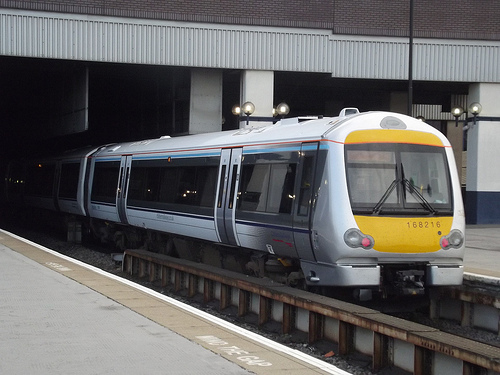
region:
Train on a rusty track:
[2, 107, 467, 304]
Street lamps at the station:
[228, 99, 481, 128]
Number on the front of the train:
[405, 219, 442, 231]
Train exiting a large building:
[2, 4, 497, 295]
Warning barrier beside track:
[0, 229, 354, 371]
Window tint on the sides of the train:
[0, 147, 325, 232]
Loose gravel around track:
[0, 232, 497, 371]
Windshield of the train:
[342, 141, 455, 221]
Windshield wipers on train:
[370, 161, 440, 219]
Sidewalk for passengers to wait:
[1, 229, 361, 374]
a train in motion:
[50, 90, 499, 365]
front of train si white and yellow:
[330, 105, 473, 302]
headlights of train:
[337, 215, 467, 264]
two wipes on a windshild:
[343, 139, 458, 220]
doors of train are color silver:
[43, 146, 315, 255]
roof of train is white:
[78, 108, 439, 145]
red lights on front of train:
[360, 229, 452, 253]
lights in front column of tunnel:
[210, 42, 296, 124]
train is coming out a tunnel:
[5, 2, 498, 293]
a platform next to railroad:
[0, 251, 470, 373]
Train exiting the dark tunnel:
[16, 108, 466, 293]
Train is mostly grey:
[25, 111, 470, 301]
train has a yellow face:
[342, 124, 463, 271]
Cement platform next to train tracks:
[0, 230, 117, 368]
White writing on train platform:
[195, 325, 275, 372]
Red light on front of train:
[355, 233, 371, 253]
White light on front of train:
[345, 231, 363, 247]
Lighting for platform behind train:
[445, 96, 484, 135]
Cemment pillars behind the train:
[238, 69, 280, 122]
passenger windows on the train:
[125, 158, 221, 223]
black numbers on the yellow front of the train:
[402, 218, 448, 233]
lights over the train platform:
[211, 95, 494, 137]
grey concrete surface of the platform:
[18, 290, 95, 372]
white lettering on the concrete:
[189, 317, 276, 372]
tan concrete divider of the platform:
[78, 260, 232, 345]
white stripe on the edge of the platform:
[182, 305, 232, 334]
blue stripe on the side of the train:
[128, 145, 320, 162]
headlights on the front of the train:
[326, 221, 479, 266]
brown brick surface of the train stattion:
[353, 5, 473, 32]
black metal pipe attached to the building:
[406, 10, 414, 111]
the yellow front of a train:
[346, 126, 458, 256]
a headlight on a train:
[343, 227, 363, 248]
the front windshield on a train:
[348, 145, 453, 213]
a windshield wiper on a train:
[397, 160, 440, 213]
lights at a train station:
[225, 100, 295, 121]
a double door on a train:
[213, 142, 246, 251]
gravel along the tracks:
[53, 238, 114, 265]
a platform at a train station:
[2, 230, 343, 373]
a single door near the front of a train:
[294, 140, 320, 268]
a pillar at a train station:
[464, 82, 498, 223]